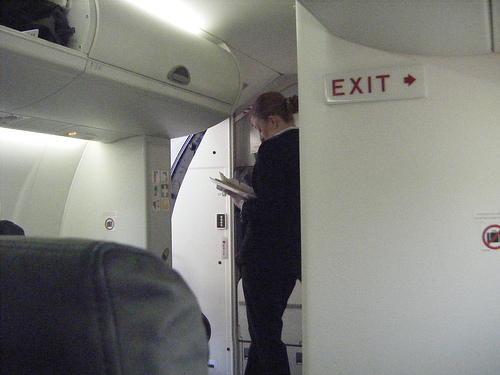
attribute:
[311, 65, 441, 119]
sign — white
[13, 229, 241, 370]
seat — gray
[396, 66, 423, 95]
arrow — red